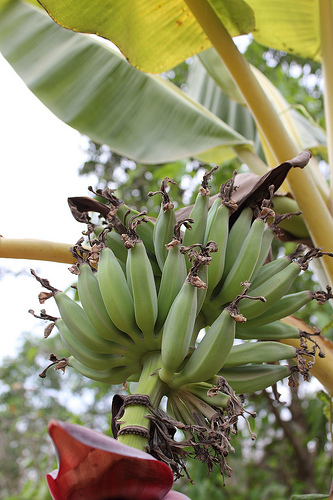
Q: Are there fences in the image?
A: No, there are no fences.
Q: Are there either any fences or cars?
A: No, there are no fences or cars.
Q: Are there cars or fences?
A: No, there are no fences or cars.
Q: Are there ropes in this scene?
A: No, there are no ropes.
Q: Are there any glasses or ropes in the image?
A: No, there are no ropes or glasses.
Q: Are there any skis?
A: No, there are no skis.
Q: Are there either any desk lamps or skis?
A: No, there are no skis or desk lamps.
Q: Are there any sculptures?
A: No, there are no sculptures.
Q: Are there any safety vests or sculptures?
A: No, there are no sculptures or safety vests.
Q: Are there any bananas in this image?
A: Yes, there is a banana.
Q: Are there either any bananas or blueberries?
A: Yes, there is a banana.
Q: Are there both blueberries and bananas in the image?
A: No, there is a banana but no blueberries.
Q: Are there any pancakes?
A: No, there are no pancakes.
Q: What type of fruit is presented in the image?
A: The fruit is a banana.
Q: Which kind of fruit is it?
A: The fruit is a banana.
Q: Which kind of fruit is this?
A: This is a banana.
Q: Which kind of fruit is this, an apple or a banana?
A: This is a banana.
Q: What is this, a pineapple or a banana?
A: This is a banana.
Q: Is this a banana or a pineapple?
A: This is a banana.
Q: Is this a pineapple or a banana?
A: This is a banana.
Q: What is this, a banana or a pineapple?
A: This is a banana.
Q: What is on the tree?
A: The banana is on the tree.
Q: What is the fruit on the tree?
A: The fruit is a banana.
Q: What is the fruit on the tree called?
A: The fruit is a banana.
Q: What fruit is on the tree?
A: The fruit is a banana.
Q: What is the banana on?
A: The banana is on the tree.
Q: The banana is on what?
A: The banana is on the tree.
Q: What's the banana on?
A: The banana is on the tree.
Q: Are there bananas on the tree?
A: Yes, there is a banana on the tree.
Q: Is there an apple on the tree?
A: No, there is a banana on the tree.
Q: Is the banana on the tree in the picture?
A: Yes, the banana is on the tree.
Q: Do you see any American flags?
A: No, there are no American flags.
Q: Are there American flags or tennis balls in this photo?
A: No, there are no American flags or tennis balls.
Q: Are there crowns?
A: No, there are no crowns.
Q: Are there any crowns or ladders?
A: No, there are no crowns or ladders.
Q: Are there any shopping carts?
A: No, there are no shopping carts.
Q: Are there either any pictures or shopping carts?
A: No, there are no shopping carts or pictures.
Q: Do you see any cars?
A: No, there are no cars.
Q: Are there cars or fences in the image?
A: No, there are no cars or fences.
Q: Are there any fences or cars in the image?
A: No, there are no cars or fences.